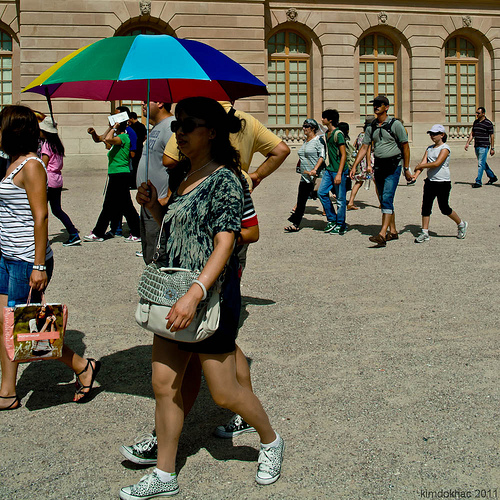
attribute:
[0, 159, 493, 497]
ground — asphalt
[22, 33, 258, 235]
umbrella — rainbow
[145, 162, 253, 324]
shirt — patterned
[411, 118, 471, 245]
person — sidewalk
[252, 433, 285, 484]
shoe — canvas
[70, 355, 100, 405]
dress shoe — casual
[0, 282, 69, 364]
bag — pink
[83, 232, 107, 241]
shoe — Nike brand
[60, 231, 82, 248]
shoe — blue, black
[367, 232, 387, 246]
shoe — brown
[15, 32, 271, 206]
umbrella — rainbow colored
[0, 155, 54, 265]
tank top — striped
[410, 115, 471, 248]
woman — hat 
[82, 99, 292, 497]
woman — white bracelet 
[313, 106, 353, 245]
boy — Young , backpack 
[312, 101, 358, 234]
man — backpack 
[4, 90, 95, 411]
woman —  striped tank top 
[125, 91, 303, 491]
woman — sunglasses 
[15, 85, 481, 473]
people — Several 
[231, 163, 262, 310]
shirts — black 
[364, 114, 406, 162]
shirt — green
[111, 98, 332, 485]
woman — black shorts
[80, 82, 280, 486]
woman —  purse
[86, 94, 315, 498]
woman — tennis shoes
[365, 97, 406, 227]
man —  blue jeans